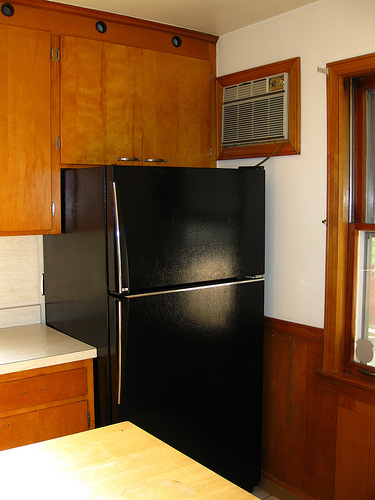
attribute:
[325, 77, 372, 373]
windowsill — wooden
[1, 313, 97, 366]
counter — laminate